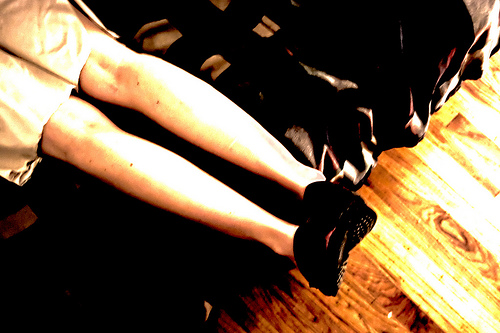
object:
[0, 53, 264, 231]
legs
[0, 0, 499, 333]
blanket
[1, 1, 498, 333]
bed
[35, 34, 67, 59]
wrinkles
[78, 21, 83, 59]
wrinkles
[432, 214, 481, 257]
umbella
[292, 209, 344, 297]
feet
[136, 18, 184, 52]
brown patch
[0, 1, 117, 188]
short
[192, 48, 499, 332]
floor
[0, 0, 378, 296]
boy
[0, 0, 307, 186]
leg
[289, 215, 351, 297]
foot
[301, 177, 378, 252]
foot